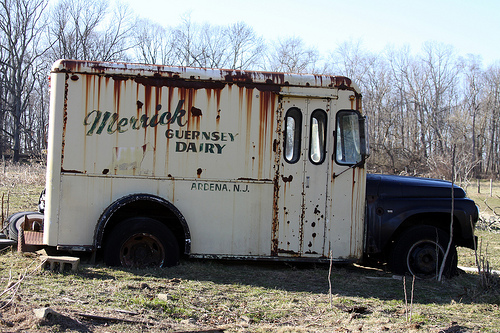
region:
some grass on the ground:
[180, 279, 350, 317]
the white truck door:
[282, 99, 323, 253]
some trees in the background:
[374, 63, 495, 165]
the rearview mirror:
[334, 110, 364, 167]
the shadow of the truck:
[158, 257, 498, 302]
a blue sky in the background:
[184, 3, 456, 24]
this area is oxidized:
[75, 68, 275, 140]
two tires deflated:
[111, 210, 456, 282]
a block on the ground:
[44, 254, 78, 274]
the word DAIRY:
[171, 140, 228, 156]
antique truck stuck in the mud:
[43, 60, 478, 275]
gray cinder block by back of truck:
[42, 254, 78, 271]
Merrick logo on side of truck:
[86, 101, 238, 153]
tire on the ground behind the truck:
[9, 209, 42, 241]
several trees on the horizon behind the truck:
[3, 1, 498, 173]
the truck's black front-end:
[366, 170, 476, 280]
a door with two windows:
[281, 95, 329, 258]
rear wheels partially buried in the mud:
[103, 224, 180, 271]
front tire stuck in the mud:
[395, 224, 456, 279]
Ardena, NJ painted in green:
[191, 177, 248, 192]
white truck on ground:
[64, 50, 448, 294]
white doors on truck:
[271, 107, 336, 259]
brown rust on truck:
[58, 75, 270, 152]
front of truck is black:
[341, 173, 478, 268]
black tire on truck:
[68, 198, 189, 318]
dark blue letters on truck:
[97, 94, 229, 179]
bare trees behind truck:
[30, 5, 490, 173]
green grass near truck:
[149, 264, 304, 322]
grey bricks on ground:
[42, 250, 79, 278]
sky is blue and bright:
[301, 4, 490, 84]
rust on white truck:
[91, 73, 268, 108]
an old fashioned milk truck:
[31, 48, 467, 275]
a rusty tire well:
[124, 236, 163, 269]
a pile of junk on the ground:
[1, 202, 45, 253]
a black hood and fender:
[369, 171, 472, 223]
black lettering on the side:
[89, 103, 239, 163]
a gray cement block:
[40, 249, 78, 276]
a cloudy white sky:
[152, 0, 478, 50]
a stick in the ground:
[323, 243, 348, 296]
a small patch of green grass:
[131, 291, 173, 313]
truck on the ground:
[26, 48, 467, 324]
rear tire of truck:
[110, 205, 176, 299]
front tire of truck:
[393, 228, 458, 290]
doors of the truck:
[277, 93, 329, 256]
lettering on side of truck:
[78, 88, 264, 197]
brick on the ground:
[38, 251, 87, 279]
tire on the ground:
[6, 213, 47, 241]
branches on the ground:
[316, 238, 497, 315]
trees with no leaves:
[6, 24, 488, 181]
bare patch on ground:
[261, 315, 352, 332]